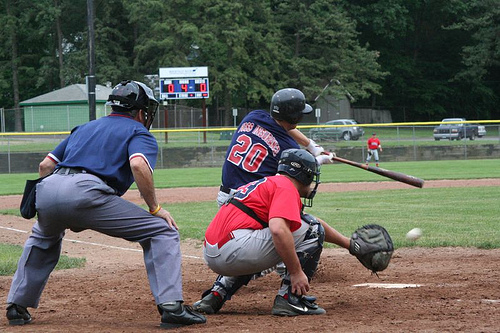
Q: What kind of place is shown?
A: It is a field.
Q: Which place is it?
A: It is a field.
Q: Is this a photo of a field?
A: Yes, it is showing a field.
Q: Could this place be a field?
A: Yes, it is a field.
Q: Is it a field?
A: Yes, it is a field.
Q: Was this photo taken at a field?
A: Yes, it was taken in a field.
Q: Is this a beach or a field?
A: It is a field.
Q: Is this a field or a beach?
A: It is a field.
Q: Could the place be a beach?
A: No, it is a field.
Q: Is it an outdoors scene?
A: Yes, it is outdoors.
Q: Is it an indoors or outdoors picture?
A: It is outdoors.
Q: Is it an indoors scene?
A: No, it is outdoors.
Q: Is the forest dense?
A: Yes, the forest is dense.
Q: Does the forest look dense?
A: Yes, the forest is dense.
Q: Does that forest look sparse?
A: No, the forest is dense.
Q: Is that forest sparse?
A: No, the forest is dense.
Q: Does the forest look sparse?
A: No, the forest is dense.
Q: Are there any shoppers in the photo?
A: No, there are no shoppers.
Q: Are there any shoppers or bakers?
A: No, there are no shoppers or bakers.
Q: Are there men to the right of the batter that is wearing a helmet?
A: Yes, there is a man to the right of the batter.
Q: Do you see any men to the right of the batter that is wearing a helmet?
A: Yes, there is a man to the right of the batter.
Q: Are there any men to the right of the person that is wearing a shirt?
A: Yes, there is a man to the right of the batter.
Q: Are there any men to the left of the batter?
A: No, the man is to the right of the batter.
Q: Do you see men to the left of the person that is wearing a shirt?
A: No, the man is to the right of the batter.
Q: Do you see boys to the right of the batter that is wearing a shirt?
A: No, there is a man to the right of the batter.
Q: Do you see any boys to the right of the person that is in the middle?
A: No, there is a man to the right of the batter.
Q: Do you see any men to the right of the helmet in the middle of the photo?
A: Yes, there is a man to the right of the helmet.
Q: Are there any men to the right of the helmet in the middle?
A: Yes, there is a man to the right of the helmet.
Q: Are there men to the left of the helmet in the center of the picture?
A: No, the man is to the right of the helmet.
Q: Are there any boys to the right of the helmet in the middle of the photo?
A: No, there is a man to the right of the helmet.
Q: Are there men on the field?
A: Yes, there is a man on the field.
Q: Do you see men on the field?
A: Yes, there is a man on the field.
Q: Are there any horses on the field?
A: No, there is a man on the field.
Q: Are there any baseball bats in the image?
A: Yes, there is a baseball bat.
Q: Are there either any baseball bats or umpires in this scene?
A: Yes, there is a baseball bat.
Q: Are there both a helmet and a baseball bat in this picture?
A: Yes, there are both a baseball bat and a helmet.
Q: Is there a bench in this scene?
A: No, there are no benches.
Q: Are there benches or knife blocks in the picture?
A: No, there are no benches or knife blocks.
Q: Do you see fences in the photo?
A: Yes, there is a fence.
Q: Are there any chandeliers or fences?
A: Yes, there is a fence.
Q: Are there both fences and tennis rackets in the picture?
A: No, there is a fence but no rackets.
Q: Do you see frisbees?
A: No, there are no frisbees.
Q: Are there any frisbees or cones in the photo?
A: No, there are no frisbees or cones.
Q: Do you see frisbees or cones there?
A: No, there are no frisbees or cones.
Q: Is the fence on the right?
A: Yes, the fence is on the right of the image.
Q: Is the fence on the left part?
A: No, the fence is on the right of the image.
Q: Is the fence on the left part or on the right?
A: The fence is on the right of the image.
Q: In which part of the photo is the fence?
A: The fence is on the right of the image.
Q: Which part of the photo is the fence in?
A: The fence is on the right of the image.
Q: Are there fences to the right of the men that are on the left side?
A: Yes, there is a fence to the right of the men.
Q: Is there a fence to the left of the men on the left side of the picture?
A: No, the fence is to the right of the men.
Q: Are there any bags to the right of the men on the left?
A: No, there is a fence to the right of the men.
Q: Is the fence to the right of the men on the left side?
A: Yes, the fence is to the right of the men.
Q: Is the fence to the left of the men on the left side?
A: No, the fence is to the right of the men.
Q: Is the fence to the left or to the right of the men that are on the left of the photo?
A: The fence is to the right of the men.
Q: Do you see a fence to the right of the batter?
A: Yes, there is a fence to the right of the batter.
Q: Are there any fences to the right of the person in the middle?
A: Yes, there is a fence to the right of the batter.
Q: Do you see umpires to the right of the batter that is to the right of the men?
A: No, there is a fence to the right of the batter.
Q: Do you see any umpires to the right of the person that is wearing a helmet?
A: No, there is a fence to the right of the batter.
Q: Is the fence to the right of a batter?
A: Yes, the fence is to the right of a batter.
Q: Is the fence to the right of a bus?
A: No, the fence is to the right of a batter.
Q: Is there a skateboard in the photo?
A: No, there are no skateboards.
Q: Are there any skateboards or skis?
A: No, there are no skateboards or skis.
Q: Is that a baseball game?
A: Yes, that is a baseball game.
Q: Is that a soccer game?
A: No, that is a baseball game.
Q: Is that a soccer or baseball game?
A: That is a baseball game.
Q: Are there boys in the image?
A: No, there are no boys.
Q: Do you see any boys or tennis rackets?
A: No, there are no boys or tennis rackets.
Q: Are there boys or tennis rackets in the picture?
A: No, there are no boys or tennis rackets.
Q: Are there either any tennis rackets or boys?
A: No, there are no boys or tennis rackets.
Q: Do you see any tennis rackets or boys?
A: No, there are no boys or tennis rackets.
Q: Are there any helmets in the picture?
A: Yes, there is a helmet.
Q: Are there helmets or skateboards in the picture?
A: Yes, there is a helmet.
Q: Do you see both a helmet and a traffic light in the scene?
A: No, there is a helmet but no traffic lights.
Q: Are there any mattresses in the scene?
A: No, there are no mattresses.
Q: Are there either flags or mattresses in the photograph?
A: No, there are no mattresses or flags.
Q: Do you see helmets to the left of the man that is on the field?
A: Yes, there is a helmet to the left of the man.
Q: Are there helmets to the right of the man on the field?
A: No, the helmet is to the left of the man.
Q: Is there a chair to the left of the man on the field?
A: No, there is a helmet to the left of the man.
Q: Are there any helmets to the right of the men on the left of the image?
A: Yes, there is a helmet to the right of the men.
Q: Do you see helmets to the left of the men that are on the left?
A: No, the helmet is to the right of the men.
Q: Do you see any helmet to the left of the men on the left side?
A: No, the helmet is to the right of the men.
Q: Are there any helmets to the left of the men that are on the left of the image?
A: No, the helmet is to the right of the men.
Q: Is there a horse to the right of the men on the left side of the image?
A: No, there is a helmet to the right of the men.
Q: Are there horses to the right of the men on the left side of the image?
A: No, there is a helmet to the right of the men.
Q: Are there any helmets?
A: Yes, there is a helmet.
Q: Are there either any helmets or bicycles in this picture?
A: Yes, there is a helmet.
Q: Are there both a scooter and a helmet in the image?
A: No, there is a helmet but no scooters.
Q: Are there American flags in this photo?
A: No, there are no American flags.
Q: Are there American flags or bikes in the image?
A: No, there are no American flags or bikes.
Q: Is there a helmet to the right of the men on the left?
A: Yes, there is a helmet to the right of the men.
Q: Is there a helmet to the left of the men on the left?
A: No, the helmet is to the right of the men.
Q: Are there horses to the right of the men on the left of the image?
A: No, there is a helmet to the right of the men.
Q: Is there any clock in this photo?
A: No, there are no clocks.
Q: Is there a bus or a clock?
A: No, there are no clocks or buses.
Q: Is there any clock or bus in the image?
A: No, there are no clocks or buses.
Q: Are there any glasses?
A: No, there are no glasses.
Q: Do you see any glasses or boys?
A: No, there are no glasses or boys.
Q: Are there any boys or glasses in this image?
A: No, there are no glasses or boys.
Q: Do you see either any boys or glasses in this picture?
A: No, there are no glasses or boys.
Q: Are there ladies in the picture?
A: No, there are no ladies.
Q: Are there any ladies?
A: No, there are no ladies.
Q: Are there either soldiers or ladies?
A: No, there are no ladies or soldiers.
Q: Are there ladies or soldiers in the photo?
A: No, there are no ladies or soldiers.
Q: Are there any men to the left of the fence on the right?
A: Yes, there are men to the left of the fence.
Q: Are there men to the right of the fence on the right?
A: No, the men are to the left of the fence.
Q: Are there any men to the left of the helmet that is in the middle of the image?
A: Yes, there are men to the left of the helmet.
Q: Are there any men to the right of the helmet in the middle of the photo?
A: No, the men are to the left of the helmet.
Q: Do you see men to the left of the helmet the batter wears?
A: Yes, there are men to the left of the helmet.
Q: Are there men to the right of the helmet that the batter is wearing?
A: No, the men are to the left of the helmet.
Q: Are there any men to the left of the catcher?
A: Yes, there are men to the left of the catcher.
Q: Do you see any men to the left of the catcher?
A: Yes, there are men to the left of the catcher.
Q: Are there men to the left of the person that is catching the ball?
A: Yes, there are men to the left of the catcher.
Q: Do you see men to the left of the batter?
A: Yes, there are men to the left of the batter.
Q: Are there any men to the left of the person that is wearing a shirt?
A: Yes, there are men to the left of the batter.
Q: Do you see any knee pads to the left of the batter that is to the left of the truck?
A: No, there are men to the left of the batter.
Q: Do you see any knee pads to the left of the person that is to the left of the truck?
A: No, there are men to the left of the batter.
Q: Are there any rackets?
A: No, there are no rackets.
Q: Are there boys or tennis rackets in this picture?
A: No, there are no tennis rackets or boys.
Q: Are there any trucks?
A: Yes, there is a truck.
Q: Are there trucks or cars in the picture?
A: Yes, there is a truck.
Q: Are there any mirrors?
A: No, there are no mirrors.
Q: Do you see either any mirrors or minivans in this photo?
A: No, there are no mirrors or minivans.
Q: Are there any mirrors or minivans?
A: No, there are no mirrors or minivans.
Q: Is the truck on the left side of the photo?
A: No, the truck is on the right of the image.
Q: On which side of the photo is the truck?
A: The truck is on the right of the image.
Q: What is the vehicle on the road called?
A: The vehicle is a truck.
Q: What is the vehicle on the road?
A: The vehicle is a truck.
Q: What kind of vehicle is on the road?
A: The vehicle is a truck.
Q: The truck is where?
A: The truck is on the road.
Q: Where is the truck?
A: The truck is on the road.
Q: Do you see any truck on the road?
A: Yes, there is a truck on the road.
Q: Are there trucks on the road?
A: Yes, there is a truck on the road.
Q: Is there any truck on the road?
A: Yes, there is a truck on the road.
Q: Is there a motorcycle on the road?
A: No, there is a truck on the road.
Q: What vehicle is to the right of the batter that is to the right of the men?
A: The vehicle is a truck.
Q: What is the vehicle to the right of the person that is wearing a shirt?
A: The vehicle is a truck.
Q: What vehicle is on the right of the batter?
A: The vehicle is a truck.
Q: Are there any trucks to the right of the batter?
A: Yes, there is a truck to the right of the batter.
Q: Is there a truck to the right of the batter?
A: Yes, there is a truck to the right of the batter.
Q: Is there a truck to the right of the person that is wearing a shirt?
A: Yes, there is a truck to the right of the batter.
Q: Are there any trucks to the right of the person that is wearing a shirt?
A: Yes, there is a truck to the right of the batter.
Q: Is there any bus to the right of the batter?
A: No, there is a truck to the right of the batter.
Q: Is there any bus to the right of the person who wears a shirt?
A: No, there is a truck to the right of the batter.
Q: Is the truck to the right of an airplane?
A: No, the truck is to the right of a batter.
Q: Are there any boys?
A: No, there are no boys.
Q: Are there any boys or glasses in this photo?
A: No, there are no boys or glasses.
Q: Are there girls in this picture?
A: No, there are no girls.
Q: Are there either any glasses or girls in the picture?
A: No, there are no girls or glasses.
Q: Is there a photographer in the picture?
A: No, there are no photographers.